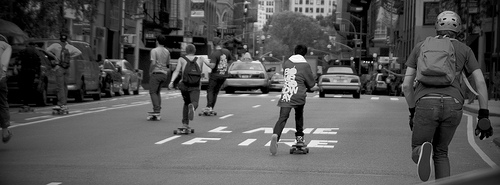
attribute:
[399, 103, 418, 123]
glove — black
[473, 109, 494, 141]
glove — black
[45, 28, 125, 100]
van — on the left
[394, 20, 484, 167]
person — running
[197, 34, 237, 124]
person — running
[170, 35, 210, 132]
person — running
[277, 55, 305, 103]
symbol — white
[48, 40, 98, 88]
backpack — small, black